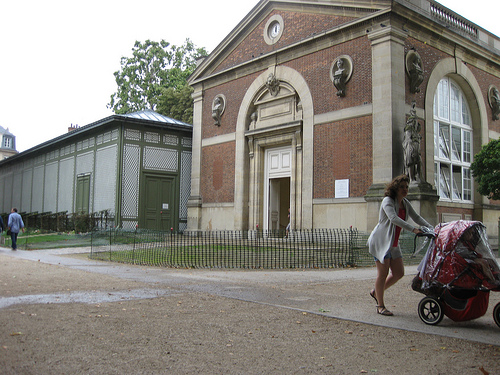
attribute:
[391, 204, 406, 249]
shirt — red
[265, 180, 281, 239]
door — open, white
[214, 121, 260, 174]
wall — green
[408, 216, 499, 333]
stroller — red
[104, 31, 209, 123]
tree — leafy